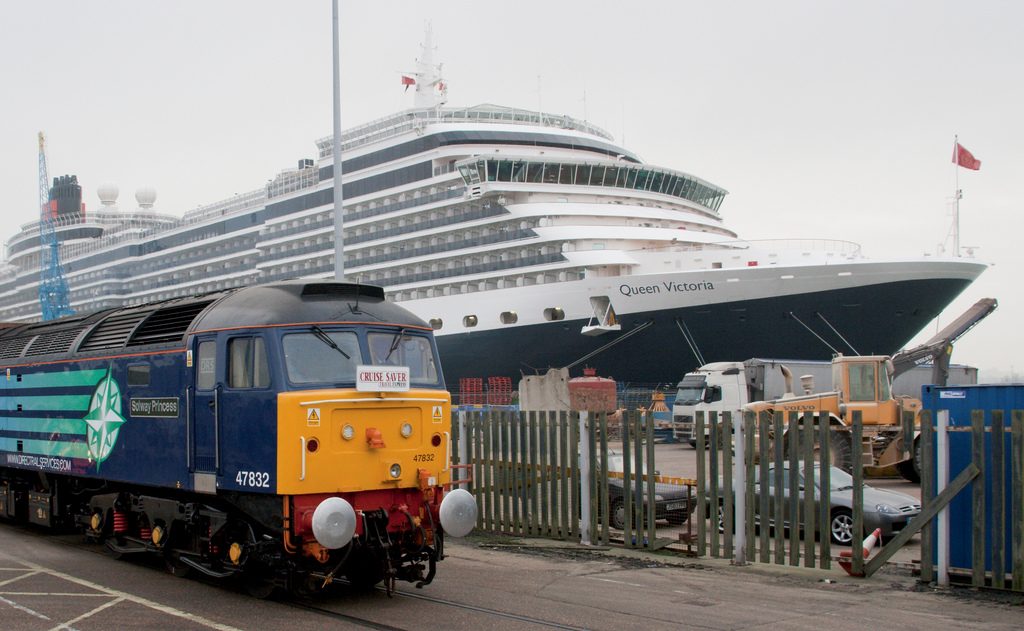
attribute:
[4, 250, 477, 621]
train — navy blue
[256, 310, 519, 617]
front — orange, red, train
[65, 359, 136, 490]
star — white, green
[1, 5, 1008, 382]
sky — gray, cloudy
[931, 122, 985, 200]
flag — red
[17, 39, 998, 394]
ship — white, blue, cruise ship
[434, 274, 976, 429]
ship — navy blue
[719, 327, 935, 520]
vehicle — orange, construction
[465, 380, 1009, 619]
fence — wooden, brown